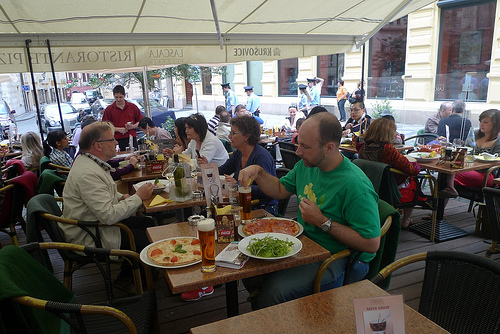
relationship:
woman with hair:
[42, 129, 74, 170] [44, 128, 65, 157]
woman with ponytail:
[42, 129, 74, 170] [40, 137, 51, 157]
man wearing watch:
[239, 110, 382, 310] [328, 204, 353, 244]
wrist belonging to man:
[319, 216, 333, 233] [239, 110, 382, 310]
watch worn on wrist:
[328, 204, 353, 244] [319, 216, 333, 233]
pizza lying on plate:
[240, 217, 301, 237] [235, 213, 305, 236]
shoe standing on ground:
[177, 277, 222, 305] [0, 109, 484, 328]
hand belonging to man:
[296, 196, 323, 225] [236, 107, 378, 307]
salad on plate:
[231, 226, 314, 271] [234, 230, 309, 262]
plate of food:
[237, 231, 302, 260] [244, 218, 298, 234]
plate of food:
[238, 217, 304, 240] [247, 236, 294, 256]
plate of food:
[237, 231, 302, 260] [148, 237, 199, 264]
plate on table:
[237, 231, 302, 260] [147, 198, 333, 295]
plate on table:
[238, 217, 304, 240] [147, 198, 333, 295]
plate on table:
[139, 235, 203, 271] [147, 198, 333, 295]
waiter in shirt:
[102, 81, 141, 146] [88, 105, 145, 133]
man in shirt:
[58, 120, 159, 292] [58, 150, 142, 260]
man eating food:
[58, 120, 159, 292] [146, 176, 166, 187]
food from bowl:
[146, 176, 166, 187] [147, 181, 168, 193]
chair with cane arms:
[364, 246, 499, 332] [366, 245, 428, 285]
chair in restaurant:
[364, 246, 499, 332] [0, 0, 498, 330]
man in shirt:
[239, 110, 382, 310] [277, 154, 379, 261]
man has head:
[236, 107, 378, 307] [290, 105, 340, 169]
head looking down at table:
[290, 105, 340, 169] [147, 198, 333, 295]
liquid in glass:
[198, 224, 217, 264] [198, 217, 217, 272]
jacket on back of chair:
[0, 243, 81, 334] [8, 241, 160, 331]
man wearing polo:
[102, 81, 137, 148] [100, 95, 145, 140]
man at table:
[58, 120, 159, 292] [0, 0, 500, 334]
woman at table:
[217, 114, 280, 217] [0, 0, 500, 334]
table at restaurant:
[0, 0, 500, 334] [0, 0, 498, 330]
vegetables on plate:
[246, 235, 293, 255] [237, 231, 302, 260]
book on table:
[209, 235, 255, 270] [186, 279, 465, 330]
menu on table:
[353, 292, 408, 332] [185, 285, 353, 332]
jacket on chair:
[0, 238, 76, 330] [0, 237, 163, 329]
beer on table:
[197, 217, 218, 274] [151, 216, 323, 286]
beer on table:
[197, 217, 218, 274] [147, 198, 333, 295]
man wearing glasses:
[58, 119, 153, 246] [98, 135, 115, 145]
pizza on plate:
[242, 218, 300, 237] [234, 212, 304, 237]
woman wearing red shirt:
[361, 113, 409, 167] [376, 147, 413, 167]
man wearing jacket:
[58, 120, 159, 292] [57, 156, 140, 250]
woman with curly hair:
[217, 114, 277, 209] [229, 117, 262, 145]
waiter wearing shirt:
[102, 85, 141, 150] [105, 106, 143, 138]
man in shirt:
[236, 107, 378, 307] [276, 148, 383, 280]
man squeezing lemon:
[236, 107, 378, 307] [237, 177, 254, 193]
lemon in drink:
[237, 177, 254, 193] [233, 181, 255, 215]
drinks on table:
[236, 182, 253, 214] [136, 202, 336, 315]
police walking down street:
[8, 73, 498, 141] [191, 98, 434, 151]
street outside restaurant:
[191, 98, 434, 151] [0, 0, 498, 330]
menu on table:
[214, 239, 249, 270] [147, 198, 333, 295]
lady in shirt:
[330, 80, 352, 127] [333, 85, 349, 102]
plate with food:
[238, 216, 303, 237] [257, 239, 287, 254]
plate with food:
[237, 231, 302, 260] [255, 217, 295, 231]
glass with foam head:
[198, 217, 217, 271] [196, 217, 213, 229]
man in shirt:
[239, 110, 382, 310] [271, 146, 386, 266]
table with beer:
[0, 0, 500, 334] [196, 222, 219, 271]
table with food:
[141, 207, 341, 299] [153, 231, 290, 265]